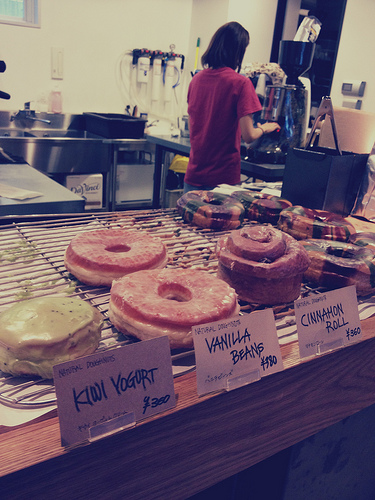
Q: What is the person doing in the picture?
A: Making a drink.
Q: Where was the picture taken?
A: In a dessert shop.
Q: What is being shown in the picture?
A: Desserts.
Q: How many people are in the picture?
A: One.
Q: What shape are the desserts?
A: Round.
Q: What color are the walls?
A: White.